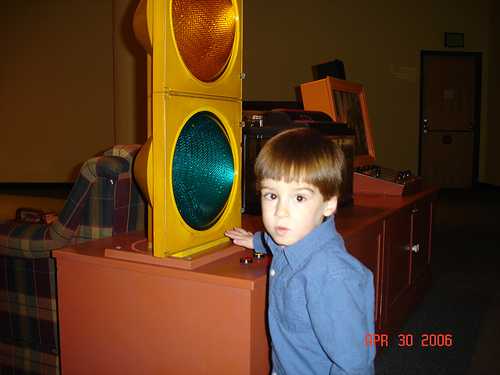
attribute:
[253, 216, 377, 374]
shirt — blue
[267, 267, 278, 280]
button — white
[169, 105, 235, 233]
light — green, shiny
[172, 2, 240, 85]
light — yellow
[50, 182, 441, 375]
table — orange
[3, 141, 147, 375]
chair — plaid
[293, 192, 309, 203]
eye — brown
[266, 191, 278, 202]
eye — brown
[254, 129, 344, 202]
hair — brown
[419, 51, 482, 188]
door — exit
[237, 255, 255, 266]
button — red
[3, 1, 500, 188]
background — orange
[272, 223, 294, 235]
mouth — red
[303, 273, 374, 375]
sleeve — blue, long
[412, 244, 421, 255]
knob — white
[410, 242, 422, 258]
opener — white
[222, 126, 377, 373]
boy — young